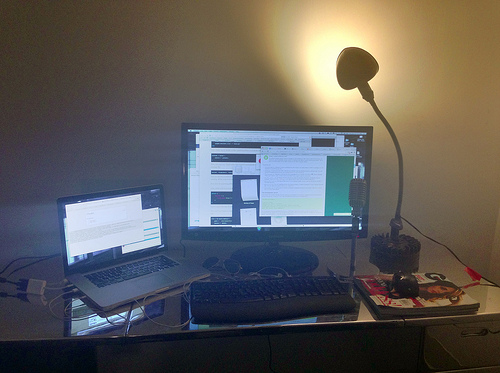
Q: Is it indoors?
A: Yes, it is indoors.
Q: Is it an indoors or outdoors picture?
A: It is indoors.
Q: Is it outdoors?
A: No, it is indoors.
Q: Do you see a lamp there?
A: Yes, there is a lamp.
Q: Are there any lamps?
A: Yes, there is a lamp.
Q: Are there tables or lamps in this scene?
A: Yes, there is a lamp.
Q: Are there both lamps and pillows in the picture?
A: No, there is a lamp but no pillows.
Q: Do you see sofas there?
A: No, there are no sofas.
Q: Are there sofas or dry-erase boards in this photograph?
A: No, there are no sofas or dry-erase boards.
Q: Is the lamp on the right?
A: Yes, the lamp is on the right of the image.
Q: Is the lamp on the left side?
A: No, the lamp is on the right of the image.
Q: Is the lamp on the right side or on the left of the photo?
A: The lamp is on the right of the image.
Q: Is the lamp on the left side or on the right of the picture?
A: The lamp is on the right of the image.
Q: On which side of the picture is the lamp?
A: The lamp is on the right of the image.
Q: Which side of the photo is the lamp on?
A: The lamp is on the right of the image.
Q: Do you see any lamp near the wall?
A: Yes, there is a lamp near the wall.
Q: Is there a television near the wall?
A: No, there is a lamp near the wall.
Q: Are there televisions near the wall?
A: No, there is a lamp near the wall.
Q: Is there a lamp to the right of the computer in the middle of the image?
A: Yes, there is a lamp to the right of the computer.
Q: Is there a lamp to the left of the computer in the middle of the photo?
A: No, the lamp is to the right of the computer.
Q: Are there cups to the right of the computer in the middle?
A: No, there is a lamp to the right of the computer.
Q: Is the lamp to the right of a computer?
A: Yes, the lamp is to the right of a computer.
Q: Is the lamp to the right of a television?
A: No, the lamp is to the right of a computer.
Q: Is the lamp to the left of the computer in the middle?
A: No, the lamp is to the right of the computer.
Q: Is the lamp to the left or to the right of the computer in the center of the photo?
A: The lamp is to the right of the computer.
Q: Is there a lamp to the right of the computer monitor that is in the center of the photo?
A: Yes, there is a lamp to the right of the computer monitor.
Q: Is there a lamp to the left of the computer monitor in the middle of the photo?
A: No, the lamp is to the right of the computer monitor.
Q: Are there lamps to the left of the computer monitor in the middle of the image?
A: No, the lamp is to the right of the computer monitor.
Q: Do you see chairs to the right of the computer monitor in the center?
A: No, there is a lamp to the right of the computer monitor.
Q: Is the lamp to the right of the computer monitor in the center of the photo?
A: Yes, the lamp is to the right of the computer monitor.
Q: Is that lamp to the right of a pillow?
A: No, the lamp is to the right of the computer monitor.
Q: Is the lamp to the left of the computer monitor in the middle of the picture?
A: No, the lamp is to the right of the computer monitor.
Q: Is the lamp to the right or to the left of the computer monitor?
A: The lamp is to the right of the computer monitor.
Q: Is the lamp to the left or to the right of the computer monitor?
A: The lamp is to the right of the computer monitor.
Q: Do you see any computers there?
A: Yes, there is a computer.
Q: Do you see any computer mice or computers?
A: Yes, there is a computer.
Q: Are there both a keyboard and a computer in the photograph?
A: Yes, there are both a computer and a keyboard.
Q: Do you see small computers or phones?
A: Yes, there is a small computer.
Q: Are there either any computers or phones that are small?
A: Yes, the computer is small.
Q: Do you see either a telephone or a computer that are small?
A: Yes, the computer is small.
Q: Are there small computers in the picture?
A: Yes, there is a small computer.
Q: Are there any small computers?
A: Yes, there is a small computer.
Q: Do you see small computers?
A: Yes, there is a small computer.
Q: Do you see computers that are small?
A: Yes, there is a small computer.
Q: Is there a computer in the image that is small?
A: Yes, there is a computer that is small.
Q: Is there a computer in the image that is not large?
A: Yes, there is a small computer.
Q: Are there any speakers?
A: No, there are no speakers.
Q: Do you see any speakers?
A: No, there are no speakers.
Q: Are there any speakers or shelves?
A: No, there are no speakers or shelves.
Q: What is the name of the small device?
A: The device is a computer.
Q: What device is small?
A: The device is a computer.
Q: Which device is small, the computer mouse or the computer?
A: The computer is small.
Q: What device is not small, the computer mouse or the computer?
A: The computer mouse is not small.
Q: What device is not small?
A: The device is a computer mouse.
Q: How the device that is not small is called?
A: The device is a computer mouse.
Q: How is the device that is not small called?
A: The device is a computer mouse.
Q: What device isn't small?
A: The device is a computer mouse.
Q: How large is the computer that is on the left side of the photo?
A: The computer is small.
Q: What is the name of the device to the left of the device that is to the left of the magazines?
A: The device is a computer.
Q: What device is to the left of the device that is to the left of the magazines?
A: The device is a computer.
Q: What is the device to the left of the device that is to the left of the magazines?
A: The device is a computer.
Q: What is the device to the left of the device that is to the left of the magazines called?
A: The device is a computer.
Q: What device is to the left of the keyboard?
A: The device is a computer.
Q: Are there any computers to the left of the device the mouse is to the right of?
A: Yes, there is a computer to the left of the keyboard.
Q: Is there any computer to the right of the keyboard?
A: No, the computer is to the left of the keyboard.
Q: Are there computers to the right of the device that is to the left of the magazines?
A: No, the computer is to the left of the keyboard.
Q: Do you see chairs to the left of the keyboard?
A: No, there is a computer to the left of the keyboard.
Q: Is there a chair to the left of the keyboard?
A: No, there is a computer to the left of the keyboard.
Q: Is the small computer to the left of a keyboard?
A: Yes, the computer is to the left of a keyboard.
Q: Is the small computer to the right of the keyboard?
A: No, the computer is to the left of the keyboard.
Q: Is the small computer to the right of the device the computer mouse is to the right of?
A: No, the computer is to the left of the keyboard.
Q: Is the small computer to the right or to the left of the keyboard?
A: The computer is to the left of the keyboard.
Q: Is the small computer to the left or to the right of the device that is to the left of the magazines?
A: The computer is to the left of the keyboard.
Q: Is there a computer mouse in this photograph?
A: Yes, there is a computer mouse.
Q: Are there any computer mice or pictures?
A: Yes, there is a computer mouse.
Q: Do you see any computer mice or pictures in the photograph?
A: Yes, there is a computer mouse.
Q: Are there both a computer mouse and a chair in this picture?
A: No, there is a computer mouse but no chairs.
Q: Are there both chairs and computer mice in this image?
A: No, there is a computer mouse but no chairs.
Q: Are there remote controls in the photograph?
A: No, there are no remote controls.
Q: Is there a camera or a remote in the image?
A: No, there are no remote controls or cameras.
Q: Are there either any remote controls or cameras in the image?
A: No, there are no remote controls or cameras.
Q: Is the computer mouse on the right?
A: Yes, the computer mouse is on the right of the image.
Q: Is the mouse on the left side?
A: No, the mouse is on the right of the image.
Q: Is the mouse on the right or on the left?
A: The mouse is on the right of the image.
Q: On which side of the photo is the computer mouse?
A: The computer mouse is on the right of the image.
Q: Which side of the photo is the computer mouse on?
A: The computer mouse is on the right of the image.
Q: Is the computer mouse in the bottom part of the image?
A: Yes, the computer mouse is in the bottom of the image.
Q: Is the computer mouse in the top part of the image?
A: No, the computer mouse is in the bottom of the image.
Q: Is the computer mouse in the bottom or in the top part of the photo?
A: The computer mouse is in the bottom of the image.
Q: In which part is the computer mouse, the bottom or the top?
A: The computer mouse is in the bottom of the image.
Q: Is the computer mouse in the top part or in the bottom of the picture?
A: The computer mouse is in the bottom of the image.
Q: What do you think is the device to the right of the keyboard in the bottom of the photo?
A: The device is a computer mouse.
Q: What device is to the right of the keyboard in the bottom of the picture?
A: The device is a computer mouse.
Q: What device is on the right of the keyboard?
A: The device is a computer mouse.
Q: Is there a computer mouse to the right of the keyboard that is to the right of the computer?
A: Yes, there is a computer mouse to the right of the keyboard.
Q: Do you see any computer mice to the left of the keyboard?
A: No, the computer mouse is to the right of the keyboard.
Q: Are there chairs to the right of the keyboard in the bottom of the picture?
A: No, there is a computer mouse to the right of the keyboard.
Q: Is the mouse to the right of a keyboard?
A: Yes, the mouse is to the right of a keyboard.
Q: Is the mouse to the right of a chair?
A: No, the mouse is to the right of a keyboard.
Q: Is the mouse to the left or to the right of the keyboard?
A: The mouse is to the right of the keyboard.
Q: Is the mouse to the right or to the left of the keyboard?
A: The mouse is to the right of the keyboard.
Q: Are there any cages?
A: No, there are no cages.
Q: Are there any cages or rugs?
A: No, there are no cages or rugs.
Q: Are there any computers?
A: Yes, there is a computer.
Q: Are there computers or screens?
A: Yes, there is a computer.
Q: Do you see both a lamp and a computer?
A: Yes, there are both a computer and a lamp.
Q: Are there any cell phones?
A: No, there are no cell phones.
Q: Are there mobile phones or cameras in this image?
A: No, there are no mobile phones or cameras.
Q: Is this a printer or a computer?
A: This is a computer.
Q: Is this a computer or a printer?
A: This is a computer.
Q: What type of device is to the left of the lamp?
A: The device is a computer.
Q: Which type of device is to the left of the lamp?
A: The device is a computer.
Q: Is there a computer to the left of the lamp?
A: Yes, there is a computer to the left of the lamp.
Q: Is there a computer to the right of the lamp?
A: No, the computer is to the left of the lamp.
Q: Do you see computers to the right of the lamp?
A: No, the computer is to the left of the lamp.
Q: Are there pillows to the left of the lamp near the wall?
A: No, there is a computer to the left of the lamp.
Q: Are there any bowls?
A: No, there are no bowls.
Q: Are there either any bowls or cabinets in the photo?
A: No, there are no bowls or cabinets.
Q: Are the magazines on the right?
A: Yes, the magazines are on the right of the image.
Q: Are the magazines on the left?
A: No, the magazines are on the right of the image.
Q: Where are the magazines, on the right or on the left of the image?
A: The magazines are on the right of the image.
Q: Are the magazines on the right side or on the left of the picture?
A: The magazines are on the right of the image.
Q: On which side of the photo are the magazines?
A: The magazines are on the right of the image.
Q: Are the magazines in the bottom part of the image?
A: Yes, the magazines are in the bottom of the image.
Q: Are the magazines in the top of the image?
A: No, the magazines are in the bottom of the image.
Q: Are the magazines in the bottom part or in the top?
A: The magazines are in the bottom of the image.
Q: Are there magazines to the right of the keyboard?
A: Yes, there are magazines to the right of the keyboard.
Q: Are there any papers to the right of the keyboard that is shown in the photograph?
A: No, there are magazines to the right of the keyboard.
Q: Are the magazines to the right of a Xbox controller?
A: No, the magazines are to the right of the keyboard.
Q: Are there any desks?
A: Yes, there is a desk.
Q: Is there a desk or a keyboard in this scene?
A: Yes, there is a desk.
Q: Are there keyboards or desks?
A: Yes, there is a desk.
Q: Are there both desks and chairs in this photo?
A: No, there is a desk but no chairs.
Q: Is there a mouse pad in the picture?
A: No, there are no mouse pads.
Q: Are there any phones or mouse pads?
A: No, there are no mouse pads or phones.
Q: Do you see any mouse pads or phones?
A: No, there are no mouse pads or phones.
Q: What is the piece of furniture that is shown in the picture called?
A: The piece of furniture is a desk.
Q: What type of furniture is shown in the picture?
A: The furniture is a desk.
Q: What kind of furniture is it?
A: The piece of furniture is a desk.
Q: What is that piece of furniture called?
A: That is a desk.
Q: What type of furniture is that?
A: That is a desk.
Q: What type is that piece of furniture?
A: That is a desk.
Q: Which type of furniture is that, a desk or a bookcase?
A: That is a desk.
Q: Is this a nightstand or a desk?
A: This is a desk.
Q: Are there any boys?
A: No, there are no boys.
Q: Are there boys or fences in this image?
A: No, there are no boys or fences.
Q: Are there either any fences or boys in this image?
A: No, there are no boys or fences.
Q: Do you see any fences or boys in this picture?
A: No, there are no boys or fences.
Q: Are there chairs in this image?
A: No, there are no chairs.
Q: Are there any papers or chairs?
A: No, there are no chairs or papers.